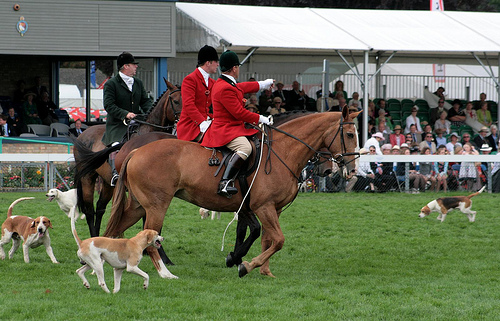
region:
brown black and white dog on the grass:
[418, 184, 488, 223]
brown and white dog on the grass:
[70, 203, 165, 293]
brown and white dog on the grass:
[1, 195, 58, 263]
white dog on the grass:
[46, 185, 84, 217]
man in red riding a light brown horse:
[101, 48, 363, 277]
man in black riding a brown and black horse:
[73, 52, 181, 234]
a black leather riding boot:
[218, 153, 245, 194]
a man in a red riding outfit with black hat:
[201, 48, 276, 195]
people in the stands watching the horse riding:
[242, 78, 497, 189]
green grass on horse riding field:
[0, 189, 499, 319]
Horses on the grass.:
[26, 19, 438, 301]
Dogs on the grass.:
[10, 193, 186, 298]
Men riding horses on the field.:
[163, 43, 278, 170]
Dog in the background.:
[422, 179, 484, 224]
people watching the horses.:
[362, 71, 494, 218]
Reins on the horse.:
[203, 61, 355, 193]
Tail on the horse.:
[56, 102, 150, 197]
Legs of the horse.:
[183, 161, 289, 303]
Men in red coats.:
[148, 17, 303, 193]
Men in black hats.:
[181, 32, 296, 105]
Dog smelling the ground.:
[414, 180, 499, 227]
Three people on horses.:
[64, 60, 360, 265]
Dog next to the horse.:
[56, 201, 181, 299]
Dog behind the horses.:
[1, 200, 69, 272]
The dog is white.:
[39, 185, 89, 225]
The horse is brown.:
[112, 101, 379, 281]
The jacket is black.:
[98, 72, 162, 145]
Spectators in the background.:
[261, 78, 498, 191]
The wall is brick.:
[1, 136, 97, 172]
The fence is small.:
[2, 159, 89, 190]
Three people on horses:
[66, 28, 371, 288]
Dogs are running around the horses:
[0, 170, 495, 307]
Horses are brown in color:
[99, 103, 378, 270]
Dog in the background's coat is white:
[38, 179, 89, 221]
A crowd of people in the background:
[5, 64, 499, 193]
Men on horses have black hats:
[102, 33, 257, 93]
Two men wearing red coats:
[161, 60, 266, 158]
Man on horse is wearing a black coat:
[95, 66, 160, 146]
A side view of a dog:
[55, 201, 180, 292]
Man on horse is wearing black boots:
[205, 145, 252, 200]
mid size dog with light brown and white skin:
[67, 223, 182, 308]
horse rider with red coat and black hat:
[203, 40, 272, 185]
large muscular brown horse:
[100, 110, 389, 211]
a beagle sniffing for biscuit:
[397, 180, 486, 231]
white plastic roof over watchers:
[209, 0, 486, 65]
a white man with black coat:
[29, 49, 166, 163]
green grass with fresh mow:
[302, 247, 463, 317]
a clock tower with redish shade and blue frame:
[1, 7, 61, 62]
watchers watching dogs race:
[376, 125, 418, 153]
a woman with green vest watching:
[477, 103, 489, 123]